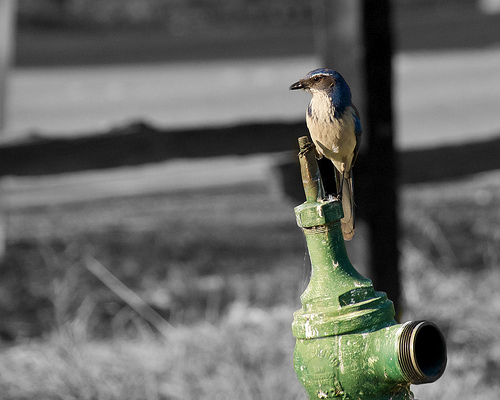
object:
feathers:
[326, 122, 352, 147]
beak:
[289, 79, 306, 89]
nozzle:
[298, 135, 328, 202]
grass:
[0, 185, 500, 400]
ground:
[0, 45, 500, 400]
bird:
[287, 67, 364, 242]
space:
[402, 316, 447, 384]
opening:
[411, 321, 448, 381]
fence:
[1, 0, 498, 325]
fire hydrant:
[290, 135, 446, 398]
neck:
[308, 90, 348, 111]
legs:
[295, 141, 322, 160]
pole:
[312, 5, 402, 334]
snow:
[2, 235, 458, 398]